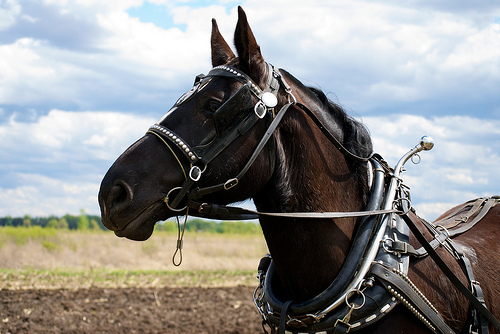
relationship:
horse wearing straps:
[95, 3, 500, 334] [211, 97, 294, 197]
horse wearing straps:
[95, 3, 500, 334] [148, 119, 200, 182]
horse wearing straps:
[95, 3, 500, 334] [188, 207, 392, 219]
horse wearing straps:
[95, 3, 500, 334] [261, 62, 286, 99]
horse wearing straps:
[95, 3, 500, 334] [395, 197, 457, 281]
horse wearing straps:
[95, 2, 499, 332] [146, 60, 391, 232]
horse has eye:
[95, 2, 499, 332] [199, 93, 238, 125]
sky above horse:
[0, 0, 498, 220] [95, 2, 499, 332]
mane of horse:
[274, 67, 372, 166] [95, 2, 499, 332]